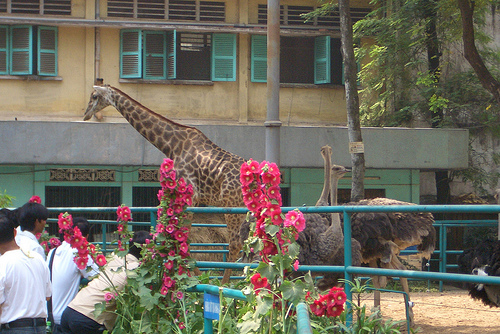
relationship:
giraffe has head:
[91, 92, 295, 257] [87, 70, 122, 129]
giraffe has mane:
[91, 92, 295, 257] [110, 78, 190, 145]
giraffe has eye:
[91, 92, 295, 257] [89, 92, 98, 99]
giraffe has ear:
[91, 92, 295, 257] [97, 77, 110, 95]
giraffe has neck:
[91, 92, 295, 257] [100, 93, 184, 147]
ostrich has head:
[331, 146, 432, 318] [311, 138, 344, 170]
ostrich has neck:
[331, 146, 432, 318] [312, 145, 335, 187]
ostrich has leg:
[331, 146, 432, 318] [371, 259, 419, 319]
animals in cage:
[94, 57, 498, 297] [43, 213, 494, 306]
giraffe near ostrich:
[91, 92, 295, 257] [331, 146, 432, 318]